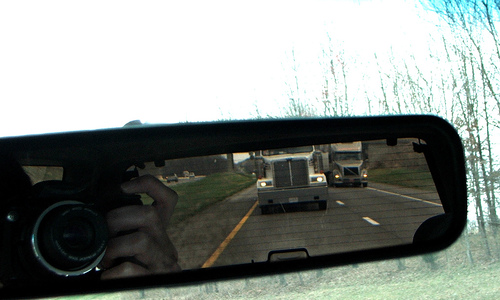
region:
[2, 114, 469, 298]
rearview mirror is black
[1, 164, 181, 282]
person holding a camera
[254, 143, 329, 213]
semi-truck with lights on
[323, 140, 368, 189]
semi-truck reflected in mirror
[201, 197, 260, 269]
yellow stripe on side of road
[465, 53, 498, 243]
tall trees outside of car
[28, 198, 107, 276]
lens on camera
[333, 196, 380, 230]
white striped lane dividers on road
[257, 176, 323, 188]
headlights on white semi-truck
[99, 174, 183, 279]
fingers holding a camera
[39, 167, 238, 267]
The person is holding a camera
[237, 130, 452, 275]
There are 2 semis in the back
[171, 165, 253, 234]
Grass separates traffic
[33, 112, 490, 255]
This is a rear view mirror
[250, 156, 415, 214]
There are 4 lights shown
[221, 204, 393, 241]
The street is black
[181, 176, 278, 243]
The grass is green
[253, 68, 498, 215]
Trees are in the background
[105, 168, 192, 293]
4 fingers are shown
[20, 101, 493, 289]
The mirror is rectangular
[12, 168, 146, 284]
black camera in hand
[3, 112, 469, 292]
car's rear view mirror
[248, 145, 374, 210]
reflection of trucks in mirror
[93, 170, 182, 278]
four fingers of person's hand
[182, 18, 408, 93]
glare of sun through trees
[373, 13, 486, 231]
trees outside window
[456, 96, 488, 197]
leaves turning brown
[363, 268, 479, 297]
green grass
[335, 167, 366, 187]
truck's headlights turned on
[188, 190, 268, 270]
yellow shoulder indicator on side of road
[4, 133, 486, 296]
Car mirror with road view.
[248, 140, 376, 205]
Two trucks with headlights on, following driver with mirror.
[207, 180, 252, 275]
Yellow line, showing edge of highway, left.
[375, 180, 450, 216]
White line, showing highway edge, right.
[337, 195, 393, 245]
White dashes, showing passing lane.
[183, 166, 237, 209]
Grassy median, separating highways and traffic.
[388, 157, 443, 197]
Grass at right edge of highway.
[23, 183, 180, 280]
Hand, showing grasped camera.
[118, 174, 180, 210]
Index finger at button.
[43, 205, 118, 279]
Lens pointed at viewer.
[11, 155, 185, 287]
CAMERA IN A REAR VIEW MIRROR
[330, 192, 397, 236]
WHITE LINES ON THE PAVEMENT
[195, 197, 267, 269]
A YELLOW LINE ON THE PAVEMENT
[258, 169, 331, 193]
TRUCK HEADLIGHTS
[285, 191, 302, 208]
A TRUCK LICENSE PLATE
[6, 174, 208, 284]
A HAND HOLDING A CAMERA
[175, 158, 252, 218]
GRASS DOWN THE CENTER OF THE STREET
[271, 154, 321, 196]
A TRUCK GRILL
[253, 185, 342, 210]
A METAL TRUCK FENDER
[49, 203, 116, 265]
A CAMERA LENSE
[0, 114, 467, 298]
image in rear view mirror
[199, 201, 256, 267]
yellow line on street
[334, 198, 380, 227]
two broken white lines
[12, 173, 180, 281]
hand holding side of camera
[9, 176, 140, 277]
lens on front of camera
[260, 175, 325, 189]
glowing headlights of truck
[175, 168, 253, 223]
grass of highway median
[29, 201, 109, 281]
Lens of a camera being used to take a picture.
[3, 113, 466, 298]
Rear view mirror with truck reflections.